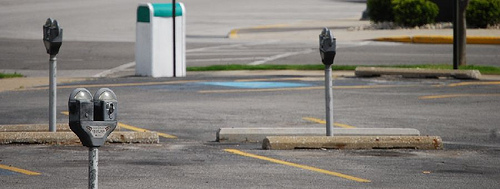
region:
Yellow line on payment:
[300, 160, 331, 186]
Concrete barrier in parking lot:
[259, 123, 453, 162]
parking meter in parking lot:
[305, 23, 351, 146]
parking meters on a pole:
[58, 82, 128, 150]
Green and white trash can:
[129, 2, 205, 86]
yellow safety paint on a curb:
[400, 26, 446, 54]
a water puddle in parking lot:
[214, 62, 313, 100]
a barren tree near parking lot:
[443, 16, 482, 81]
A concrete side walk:
[267, 26, 302, 41]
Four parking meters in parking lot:
[30, 14, 130, 178]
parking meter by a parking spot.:
[274, 17, 416, 147]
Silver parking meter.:
[47, 79, 140, 184]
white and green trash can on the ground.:
[131, 2, 228, 74]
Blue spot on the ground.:
[222, 44, 297, 129]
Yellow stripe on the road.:
[230, 136, 342, 181]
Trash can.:
[128, 3, 223, 90]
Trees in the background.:
[377, 4, 492, 74]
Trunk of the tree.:
[433, 4, 491, 87]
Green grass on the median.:
[229, 39, 306, 80]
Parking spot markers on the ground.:
[226, 109, 441, 170]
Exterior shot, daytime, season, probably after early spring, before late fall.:
[5, 0, 497, 185]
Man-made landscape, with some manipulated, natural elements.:
[1, 1, 496, 181]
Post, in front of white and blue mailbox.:
[135, 2, 186, 79]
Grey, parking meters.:
[30, 15, 395, 185]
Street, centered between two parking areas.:
[1, 0, 496, 180]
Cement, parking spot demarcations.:
[10, 106, 435, 151]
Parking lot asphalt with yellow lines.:
[10, 81, 495, 181]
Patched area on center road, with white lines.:
[15, 25, 300, 61]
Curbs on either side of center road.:
[370, 22, 496, 84]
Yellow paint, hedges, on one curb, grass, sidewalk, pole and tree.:
[376, 23, 487, 86]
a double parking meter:
[77, 67, 128, 187]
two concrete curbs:
[165, 124, 465, 151]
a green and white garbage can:
[107, 8, 199, 78]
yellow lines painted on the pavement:
[11, 133, 385, 188]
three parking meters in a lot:
[8, 17, 363, 155]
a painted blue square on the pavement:
[179, 70, 316, 103]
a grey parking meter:
[70, 77, 133, 152]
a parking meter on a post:
[317, 19, 349, 145]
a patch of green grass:
[193, 54, 318, 88]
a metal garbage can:
[112, 7, 187, 77]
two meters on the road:
[66, 87, 119, 187]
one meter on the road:
[312, 25, 342, 138]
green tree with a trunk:
[353, 3, 498, 75]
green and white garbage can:
[134, 3, 185, 72]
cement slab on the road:
[252, 132, 446, 155]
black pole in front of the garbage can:
[166, 0, 181, 76]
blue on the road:
[200, 74, 312, 100]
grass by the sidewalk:
[220, 60, 277, 77]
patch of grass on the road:
[3, 71, 34, 83]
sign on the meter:
[83, 125, 111, 143]